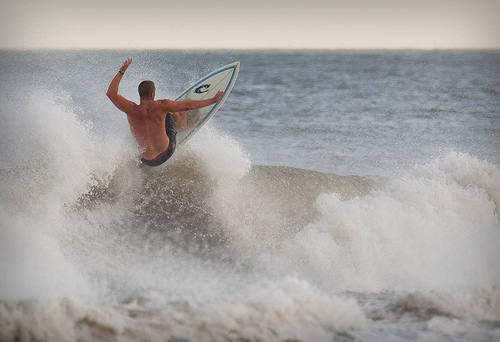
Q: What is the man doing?
A: Surfing.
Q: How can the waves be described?
A: Rough.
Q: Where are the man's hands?
A: One is on the surfboard and the other is in the air.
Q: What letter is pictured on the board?
A: A "C.".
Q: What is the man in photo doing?
A: Surfing.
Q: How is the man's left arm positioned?
A: Raised upwards.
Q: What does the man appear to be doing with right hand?
A: Holding surfboard.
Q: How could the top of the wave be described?
A: Frothy.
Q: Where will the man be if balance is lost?
A: In ocean.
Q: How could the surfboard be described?
A: White with green trim.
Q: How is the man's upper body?
A: Bare.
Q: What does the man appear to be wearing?
A: Swim trunks.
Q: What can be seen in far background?
A: Sky.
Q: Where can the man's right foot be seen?
A: On surfboard.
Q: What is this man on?
A: A surfboard.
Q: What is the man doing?
A: Surfing.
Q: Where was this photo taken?
A: The ocean.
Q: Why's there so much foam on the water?
A: It's a large wave.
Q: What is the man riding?
A: A surfboard.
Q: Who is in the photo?
A: A man.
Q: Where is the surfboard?
A: In water.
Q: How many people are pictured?
A: One.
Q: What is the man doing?
A: Riding a wave.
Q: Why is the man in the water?
A: For fun.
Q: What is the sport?
A: Water surfing.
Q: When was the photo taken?
A: Daytime.